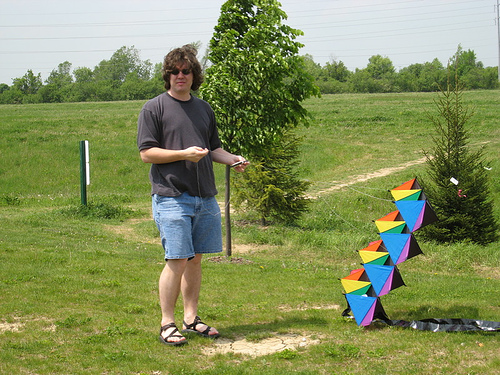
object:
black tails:
[377, 304, 500, 337]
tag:
[448, 175, 458, 187]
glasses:
[171, 68, 195, 78]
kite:
[337, 175, 499, 337]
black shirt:
[136, 90, 221, 200]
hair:
[157, 42, 206, 92]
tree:
[407, 71, 498, 245]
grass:
[0, 89, 499, 374]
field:
[0, 89, 499, 374]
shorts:
[150, 190, 223, 263]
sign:
[80, 140, 89, 185]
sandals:
[157, 322, 190, 346]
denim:
[152, 192, 222, 261]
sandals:
[180, 314, 220, 339]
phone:
[224, 158, 252, 168]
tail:
[375, 298, 499, 337]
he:
[135, 42, 251, 346]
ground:
[0, 90, 499, 374]